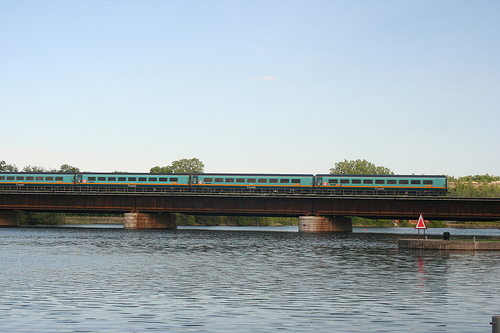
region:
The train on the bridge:
[0, 171, 448, 196]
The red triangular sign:
[414, 209, 428, 232]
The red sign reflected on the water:
[411, 253, 431, 278]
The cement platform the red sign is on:
[396, 231, 499, 253]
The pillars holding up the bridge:
[0, 212, 357, 234]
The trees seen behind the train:
[0, 152, 400, 177]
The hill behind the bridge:
[0, 158, 497, 225]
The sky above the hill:
[0, 2, 498, 177]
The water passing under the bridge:
[0, 221, 498, 331]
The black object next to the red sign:
[439, 226, 453, 241]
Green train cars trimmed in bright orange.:
[5, 161, 453, 191]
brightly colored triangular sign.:
[410, 210, 434, 234]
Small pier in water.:
[394, 227, 496, 257]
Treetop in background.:
[150, 156, 214, 171]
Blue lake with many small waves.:
[5, 227, 489, 324]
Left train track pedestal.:
[118, 207, 186, 234]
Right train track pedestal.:
[295, 213, 360, 242]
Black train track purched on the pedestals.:
[2, 192, 497, 209]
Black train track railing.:
[2, 185, 499, 197]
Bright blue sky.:
[2, 0, 491, 102]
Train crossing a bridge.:
[11, 60, 490, 306]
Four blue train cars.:
[4, 151, 462, 213]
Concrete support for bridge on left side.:
[110, 211, 181, 236]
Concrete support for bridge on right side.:
[291, 204, 357, 238]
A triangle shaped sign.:
[408, 206, 433, 233]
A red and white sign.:
[406, 210, 436, 242]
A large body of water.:
[15, 217, 481, 329]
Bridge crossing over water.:
[10, 114, 493, 329]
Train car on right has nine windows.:
[317, 165, 455, 202]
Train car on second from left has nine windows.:
[76, 161, 193, 193]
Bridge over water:
[30, 182, 473, 212]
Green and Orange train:
[316, 176, 456, 192]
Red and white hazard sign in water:
[408, 212, 431, 234]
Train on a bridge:
[11, 172, 453, 193]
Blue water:
[116, 239, 341, 315]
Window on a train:
[89, 177, 181, 182]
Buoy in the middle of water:
[443, 225, 455, 238]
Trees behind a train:
[324, 152, 410, 177]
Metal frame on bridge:
[93, 182, 325, 218]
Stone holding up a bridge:
[298, 215, 330, 228]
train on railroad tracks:
[6, 140, 499, 195]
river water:
[85, 232, 365, 324]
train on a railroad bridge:
[25, 145, 484, 228]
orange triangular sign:
[410, 210, 432, 232]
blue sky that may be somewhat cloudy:
[37, 16, 345, 111]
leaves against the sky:
[15, 125, 435, 170]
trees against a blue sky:
[136, 130, 446, 170]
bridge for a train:
[8, 186, 393, 242]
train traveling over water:
[22, 136, 458, 282]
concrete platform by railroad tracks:
[401, 234, 498, 255]